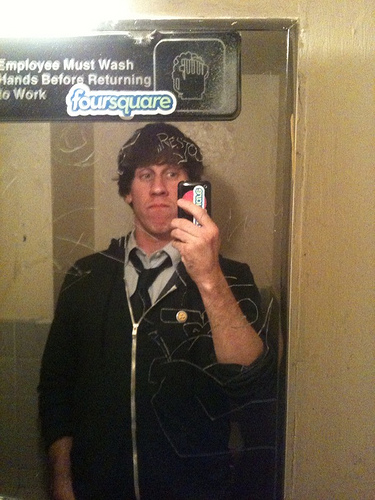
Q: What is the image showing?
A: It is showing a bathroom.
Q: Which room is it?
A: It is a bathroom.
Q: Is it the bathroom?
A: Yes, it is the bathroom.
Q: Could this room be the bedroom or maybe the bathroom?
A: It is the bathroom.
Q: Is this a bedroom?
A: No, it is a bathroom.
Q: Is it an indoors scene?
A: Yes, it is indoors.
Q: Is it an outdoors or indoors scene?
A: It is indoors.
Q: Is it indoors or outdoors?
A: It is indoors.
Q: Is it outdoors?
A: No, it is indoors.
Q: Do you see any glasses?
A: No, there are no glasses.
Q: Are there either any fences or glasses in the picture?
A: No, there are no glasses or fences.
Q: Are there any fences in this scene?
A: No, there are no fences.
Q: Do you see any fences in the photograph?
A: No, there are no fences.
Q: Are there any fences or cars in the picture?
A: No, there are no fences or cars.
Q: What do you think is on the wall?
A: The sign is on the wall.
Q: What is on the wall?
A: The sign is on the wall.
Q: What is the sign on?
A: The sign is on the wall.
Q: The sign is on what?
A: The sign is on the wall.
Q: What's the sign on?
A: The sign is on the wall.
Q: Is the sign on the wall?
A: Yes, the sign is on the wall.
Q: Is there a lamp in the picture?
A: No, there are no lamps.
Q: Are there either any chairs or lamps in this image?
A: No, there are no lamps or chairs.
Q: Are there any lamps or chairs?
A: No, there are no lamps or chairs.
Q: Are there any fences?
A: No, there are no fences.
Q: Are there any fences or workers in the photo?
A: No, there are no fences or workers.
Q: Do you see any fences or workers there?
A: No, there are no fences or workers.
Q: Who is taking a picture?
A: The man is taking a picture.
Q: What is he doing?
A: The man is taking a picture.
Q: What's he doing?
A: The man is taking a picture.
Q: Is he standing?
A: Yes, the man is standing.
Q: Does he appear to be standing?
A: Yes, the man is standing.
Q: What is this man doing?
A: The man is standing.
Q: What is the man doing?
A: The man is standing.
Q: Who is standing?
A: The man is standing.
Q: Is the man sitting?
A: No, the man is standing.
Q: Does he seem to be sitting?
A: No, the man is standing.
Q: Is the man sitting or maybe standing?
A: The man is standing.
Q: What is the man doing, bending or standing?
A: The man is standing.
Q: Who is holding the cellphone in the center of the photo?
A: The man is holding the mobile phone.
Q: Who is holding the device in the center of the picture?
A: The man is holding the mobile phone.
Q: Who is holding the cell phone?
A: The man is holding the mobile phone.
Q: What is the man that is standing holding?
A: The man is holding the mobile phone.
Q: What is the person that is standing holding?
A: The man is holding the mobile phone.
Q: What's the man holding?
A: The man is holding the mobile phone.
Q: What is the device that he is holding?
A: The device is a cell phone.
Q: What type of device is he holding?
A: The man is holding the cell phone.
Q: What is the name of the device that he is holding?
A: The device is a cell phone.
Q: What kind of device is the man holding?
A: The man is holding the cell phone.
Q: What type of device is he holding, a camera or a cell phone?
A: The man is holding a cell phone.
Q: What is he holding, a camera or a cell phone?
A: The man is holding a cell phone.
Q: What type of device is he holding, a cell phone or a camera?
A: The man is holding a cell phone.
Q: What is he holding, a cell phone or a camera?
A: The man is holding a cell phone.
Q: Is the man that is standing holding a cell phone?
A: Yes, the man is holding a cell phone.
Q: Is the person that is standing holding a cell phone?
A: Yes, the man is holding a cell phone.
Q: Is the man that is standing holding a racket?
A: No, the man is holding a cell phone.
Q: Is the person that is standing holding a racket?
A: No, the man is holding a cell phone.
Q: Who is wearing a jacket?
A: The man is wearing a jacket.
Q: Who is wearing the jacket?
A: The man is wearing a jacket.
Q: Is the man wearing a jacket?
A: Yes, the man is wearing a jacket.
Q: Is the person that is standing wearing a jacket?
A: Yes, the man is wearing a jacket.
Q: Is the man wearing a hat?
A: No, the man is wearing a jacket.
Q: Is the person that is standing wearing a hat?
A: No, the man is wearing a jacket.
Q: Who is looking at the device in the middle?
A: The man is looking at the cell phone.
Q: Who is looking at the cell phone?
A: The man is looking at the cell phone.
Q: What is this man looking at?
A: The man is looking at the mobile phone.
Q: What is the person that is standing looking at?
A: The man is looking at the mobile phone.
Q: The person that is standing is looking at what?
A: The man is looking at the mobile phone.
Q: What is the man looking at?
A: The man is looking at the mobile phone.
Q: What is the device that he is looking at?
A: The device is a cell phone.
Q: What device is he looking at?
A: The man is looking at the mobile phone.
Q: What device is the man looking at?
A: The man is looking at the mobile phone.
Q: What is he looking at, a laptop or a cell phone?
A: The man is looking at a cell phone.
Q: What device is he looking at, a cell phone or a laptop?
A: The man is looking at a cell phone.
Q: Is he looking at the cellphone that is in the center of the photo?
A: Yes, the man is looking at the cell phone.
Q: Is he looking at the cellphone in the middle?
A: Yes, the man is looking at the cell phone.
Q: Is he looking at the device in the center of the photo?
A: Yes, the man is looking at the cell phone.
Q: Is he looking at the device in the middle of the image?
A: Yes, the man is looking at the cell phone.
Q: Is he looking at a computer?
A: No, the man is looking at the cell phone.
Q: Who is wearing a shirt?
A: The man is wearing a shirt.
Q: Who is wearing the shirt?
A: The man is wearing a shirt.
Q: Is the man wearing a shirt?
A: Yes, the man is wearing a shirt.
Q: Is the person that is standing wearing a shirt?
A: Yes, the man is wearing a shirt.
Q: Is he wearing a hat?
A: No, the man is wearing a shirt.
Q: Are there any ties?
A: Yes, there is a tie.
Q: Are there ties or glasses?
A: Yes, there is a tie.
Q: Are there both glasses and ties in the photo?
A: No, there is a tie but no glasses.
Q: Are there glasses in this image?
A: No, there are no glasses.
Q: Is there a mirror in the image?
A: Yes, there is a mirror.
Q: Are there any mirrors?
A: Yes, there is a mirror.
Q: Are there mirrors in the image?
A: Yes, there is a mirror.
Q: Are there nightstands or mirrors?
A: Yes, there is a mirror.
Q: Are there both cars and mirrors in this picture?
A: No, there is a mirror but no cars.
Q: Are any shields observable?
A: No, there are no shields.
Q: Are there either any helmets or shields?
A: No, there are no shields or helmets.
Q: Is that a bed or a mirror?
A: That is a mirror.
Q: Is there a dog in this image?
A: No, there are no dogs.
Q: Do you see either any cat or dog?
A: No, there are no dogs or cats.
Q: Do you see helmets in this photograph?
A: No, there are no helmets.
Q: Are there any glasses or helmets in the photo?
A: No, there are no helmets or glasses.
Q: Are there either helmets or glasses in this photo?
A: No, there are no helmets or glasses.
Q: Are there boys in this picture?
A: No, there are no boys.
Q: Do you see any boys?
A: No, there are no boys.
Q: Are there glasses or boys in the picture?
A: No, there are no boys or glasses.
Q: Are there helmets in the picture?
A: No, there are no helmets.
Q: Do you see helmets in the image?
A: No, there are no helmets.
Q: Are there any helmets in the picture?
A: No, there are no helmets.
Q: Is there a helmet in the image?
A: No, there are no helmets.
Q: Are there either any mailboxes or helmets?
A: No, there are no helmets or mailboxes.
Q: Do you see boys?
A: No, there are no boys.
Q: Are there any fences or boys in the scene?
A: No, there are no boys or fences.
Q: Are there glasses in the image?
A: No, there are no glasses.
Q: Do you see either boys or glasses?
A: No, there are no glasses or boys.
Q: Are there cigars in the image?
A: No, there are no cigars.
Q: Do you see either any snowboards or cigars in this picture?
A: No, there are no cigars or snowboards.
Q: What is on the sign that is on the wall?
A: The symbol is on the sign.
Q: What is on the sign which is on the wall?
A: The symbol is on the sign.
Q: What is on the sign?
A: The symbol is on the sign.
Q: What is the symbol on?
A: The symbol is on the sign.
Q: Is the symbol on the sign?
A: Yes, the symbol is on the sign.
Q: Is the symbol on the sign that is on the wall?
A: Yes, the symbol is on the sign.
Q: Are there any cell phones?
A: Yes, there is a cell phone.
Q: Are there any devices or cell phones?
A: Yes, there is a cell phone.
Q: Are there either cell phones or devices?
A: Yes, there is a cell phone.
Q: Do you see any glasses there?
A: No, there are no glasses.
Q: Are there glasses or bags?
A: No, there are no glasses or bags.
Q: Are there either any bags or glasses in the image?
A: No, there are no glasses or bags.